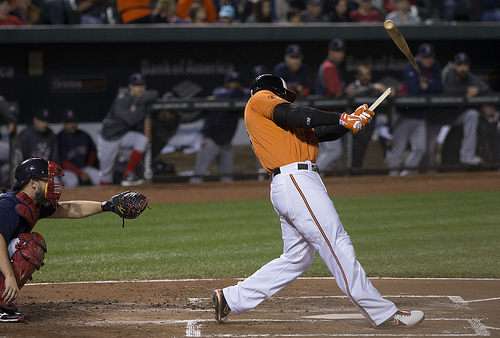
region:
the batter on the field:
[204, 58, 441, 328]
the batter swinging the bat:
[156, 35, 441, 335]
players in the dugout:
[96, 68, 498, 165]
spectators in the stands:
[7, 5, 494, 22]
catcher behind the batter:
[5, 151, 161, 332]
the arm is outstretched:
[66, 190, 166, 217]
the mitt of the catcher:
[101, 186, 151, 221]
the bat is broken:
[317, 5, 497, 125]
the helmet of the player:
[215, 50, 300, 100]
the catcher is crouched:
[11, 159, 142, 329]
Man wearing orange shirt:
[241, 89, 321, 166]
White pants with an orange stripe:
[222, 158, 400, 323]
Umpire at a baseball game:
[0, 155, 150, 322]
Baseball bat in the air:
[378, 15, 433, 95]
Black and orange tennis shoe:
[210, 281, 233, 324]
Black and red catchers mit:
[100, 188, 149, 220]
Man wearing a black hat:
[248, 71, 299, 101]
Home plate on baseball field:
[306, 301, 388, 325]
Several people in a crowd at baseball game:
[99, 3, 331, 25]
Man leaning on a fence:
[94, 71, 181, 196]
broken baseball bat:
[340, 14, 445, 137]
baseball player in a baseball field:
[195, 13, 454, 328]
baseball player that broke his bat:
[187, 9, 444, 333]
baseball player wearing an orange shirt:
[187, 14, 460, 324]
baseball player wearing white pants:
[189, 16, 454, 326]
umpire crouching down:
[0, 141, 155, 320]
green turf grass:
[0, 193, 497, 283]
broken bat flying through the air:
[351, 10, 426, 131]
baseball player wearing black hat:
[187, 44, 442, 331]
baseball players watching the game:
[0, 34, 495, 189]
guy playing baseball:
[198, 4, 435, 335]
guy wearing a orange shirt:
[197, 60, 434, 336]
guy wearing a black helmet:
[209, 63, 415, 336]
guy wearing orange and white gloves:
[208, 55, 433, 337]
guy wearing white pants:
[215, 55, 425, 335]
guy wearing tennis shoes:
[201, 53, 439, 335]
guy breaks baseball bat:
[194, 11, 456, 336]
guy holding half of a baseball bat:
[211, 64, 431, 334]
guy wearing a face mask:
[0, 148, 152, 336]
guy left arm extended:
[0, 148, 153, 337]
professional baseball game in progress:
[15, 22, 485, 326]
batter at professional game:
[205, 60, 422, 331]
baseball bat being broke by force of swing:
[350, 9, 423, 143]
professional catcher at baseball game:
[5, 150, 149, 327]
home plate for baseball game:
[292, 308, 369, 325]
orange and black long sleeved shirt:
[244, 88, 341, 170]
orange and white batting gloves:
[338, 100, 375, 140]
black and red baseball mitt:
[114, 189, 150, 221]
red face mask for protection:
[44, 161, 64, 215]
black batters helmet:
[251, 72, 293, 91]